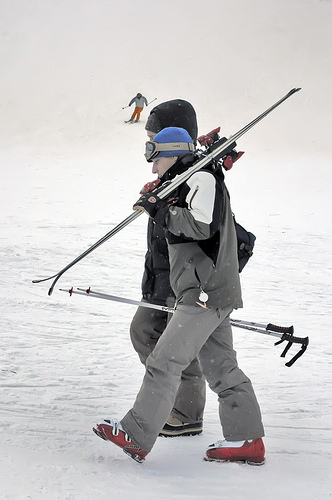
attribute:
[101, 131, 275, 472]
man — walking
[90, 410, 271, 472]
boots — white, red, snow boots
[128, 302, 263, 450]
pants — gray, orange, grey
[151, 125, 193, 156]
hat — blue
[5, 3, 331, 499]
ground — snowy, snow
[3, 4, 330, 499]
snow — white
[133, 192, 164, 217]
gloves — black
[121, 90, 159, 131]
person — skiing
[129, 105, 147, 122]
pants — orange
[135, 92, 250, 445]
man — skiing downhill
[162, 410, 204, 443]
boots — black, brown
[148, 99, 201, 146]
hat — black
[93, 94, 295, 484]
people — skiers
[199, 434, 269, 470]
boot — red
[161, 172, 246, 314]
jacket — puffy, gray, black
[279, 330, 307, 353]
handle — black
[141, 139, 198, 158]
goggles — gray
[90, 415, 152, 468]
boot — red, ski boot